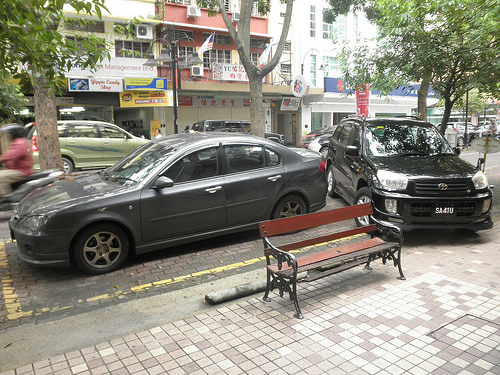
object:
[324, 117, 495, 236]
black car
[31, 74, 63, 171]
brown trunk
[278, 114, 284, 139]
door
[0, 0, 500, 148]
building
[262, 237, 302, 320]
side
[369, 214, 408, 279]
side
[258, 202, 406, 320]
bench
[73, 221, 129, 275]
tire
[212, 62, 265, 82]
sign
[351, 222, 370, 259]
ground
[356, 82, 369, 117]
banner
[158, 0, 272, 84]
frame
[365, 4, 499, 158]
tree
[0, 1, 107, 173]
tree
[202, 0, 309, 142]
tree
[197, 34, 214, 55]
flag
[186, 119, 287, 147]
car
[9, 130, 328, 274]
car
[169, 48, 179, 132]
post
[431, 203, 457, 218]
plate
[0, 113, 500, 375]
road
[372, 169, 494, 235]
front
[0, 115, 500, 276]
parked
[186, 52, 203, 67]
lights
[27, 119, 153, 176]
car